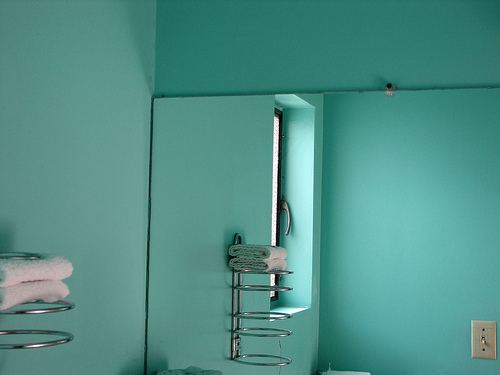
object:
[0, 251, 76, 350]
towel rack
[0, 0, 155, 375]
wall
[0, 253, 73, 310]
towels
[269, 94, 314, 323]
window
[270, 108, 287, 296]
mirror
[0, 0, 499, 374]
bathroom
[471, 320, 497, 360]
light switch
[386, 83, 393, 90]
screw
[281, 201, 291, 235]
window handle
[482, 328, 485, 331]
bolt